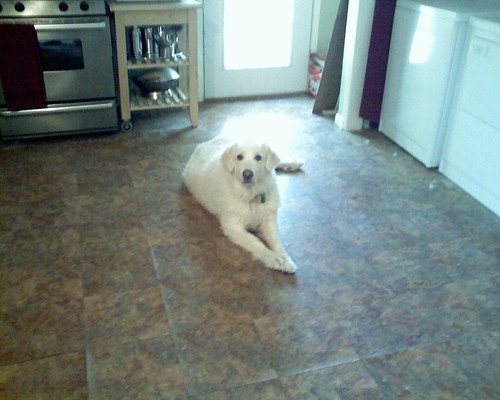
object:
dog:
[180, 128, 305, 274]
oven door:
[3, 15, 117, 101]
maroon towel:
[0, 25, 47, 112]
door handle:
[13, 18, 106, 24]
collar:
[257, 193, 264, 203]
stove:
[2, 0, 134, 144]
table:
[68, 1, 218, 96]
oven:
[0, 2, 119, 142]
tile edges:
[459, 186, 497, 214]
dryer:
[378, 0, 468, 169]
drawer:
[0, 100, 119, 142]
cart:
[106, 0, 200, 133]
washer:
[377, 0, 469, 169]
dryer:
[437, 15, 500, 219]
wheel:
[121, 122, 133, 133]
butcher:
[106, 0, 203, 132]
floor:
[0, 1, 499, 398]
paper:
[429, 178, 456, 189]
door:
[203, 0, 314, 100]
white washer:
[384, 1, 464, 161]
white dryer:
[438, 12, 499, 218]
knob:
[79, 2, 90, 12]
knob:
[59, 1, 68, 11]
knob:
[14, 2, 25, 12]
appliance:
[0, 0, 119, 139]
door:
[0, 15, 116, 108]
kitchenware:
[153, 33, 179, 57]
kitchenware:
[131, 67, 181, 101]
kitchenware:
[132, 26, 143, 60]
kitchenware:
[145, 27, 154, 58]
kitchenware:
[157, 26, 163, 58]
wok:
[132, 66, 181, 98]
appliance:
[377, 0, 467, 168]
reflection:
[408, 4, 437, 65]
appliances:
[438, 14, 500, 219]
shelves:
[128, 58, 189, 69]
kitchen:
[0, 2, 498, 399]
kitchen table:
[108, 1, 205, 133]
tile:
[170, 319, 279, 397]